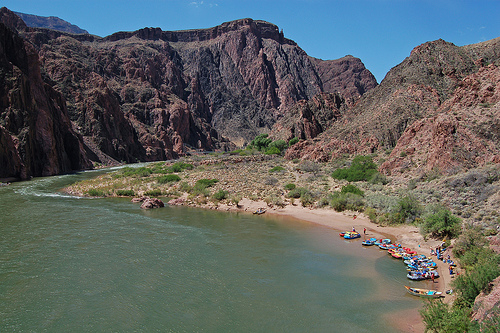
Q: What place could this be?
A: It is a beach.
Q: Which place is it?
A: It is a beach.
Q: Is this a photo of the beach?
A: Yes, it is showing the beach.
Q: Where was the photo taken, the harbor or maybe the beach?
A: It was taken at the beach.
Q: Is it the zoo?
A: No, it is the beach.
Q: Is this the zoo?
A: No, it is the beach.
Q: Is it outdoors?
A: Yes, it is outdoors.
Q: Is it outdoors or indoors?
A: It is outdoors.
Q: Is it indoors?
A: No, it is outdoors.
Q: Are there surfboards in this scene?
A: No, there are no surfboards.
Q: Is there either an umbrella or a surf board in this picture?
A: No, there are no surfboards or umbrellas.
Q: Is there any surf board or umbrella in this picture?
A: No, there are no surfboards or umbrellas.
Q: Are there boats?
A: Yes, there is a boat.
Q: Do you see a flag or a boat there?
A: Yes, there is a boat.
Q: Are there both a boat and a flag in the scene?
A: No, there is a boat but no flags.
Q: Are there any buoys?
A: No, there are no buoys.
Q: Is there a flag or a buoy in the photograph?
A: No, there are no buoys or flags.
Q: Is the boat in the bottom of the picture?
A: Yes, the boat is in the bottom of the image.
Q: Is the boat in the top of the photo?
A: No, the boat is in the bottom of the image.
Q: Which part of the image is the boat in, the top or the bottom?
A: The boat is in the bottom of the image.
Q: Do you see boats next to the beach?
A: Yes, there is a boat next to the beach.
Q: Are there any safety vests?
A: No, there are no safety vests.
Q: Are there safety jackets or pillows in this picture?
A: No, there are no safety jackets or pillows.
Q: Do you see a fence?
A: No, there are no fences.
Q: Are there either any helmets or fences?
A: No, there are no fences or helmets.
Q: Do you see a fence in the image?
A: No, there are no fences.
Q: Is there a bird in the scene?
A: No, there are no birds.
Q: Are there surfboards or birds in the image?
A: No, there are no birds or surfboards.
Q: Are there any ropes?
A: No, there are no ropes.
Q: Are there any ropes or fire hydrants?
A: No, there are no ropes or fire hydrants.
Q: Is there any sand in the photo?
A: Yes, there is sand.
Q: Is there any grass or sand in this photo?
A: Yes, there is sand.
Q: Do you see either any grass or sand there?
A: Yes, there is sand.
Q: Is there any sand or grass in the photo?
A: Yes, there is sand.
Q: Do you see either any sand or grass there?
A: Yes, there is sand.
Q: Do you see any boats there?
A: Yes, there is a boat.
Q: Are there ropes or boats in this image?
A: Yes, there is a boat.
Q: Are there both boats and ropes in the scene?
A: No, there is a boat but no ropes.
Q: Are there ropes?
A: No, there are no ropes.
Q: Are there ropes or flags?
A: No, there are no ropes or flags.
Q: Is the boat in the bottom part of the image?
A: Yes, the boat is in the bottom of the image.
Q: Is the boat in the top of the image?
A: No, the boat is in the bottom of the image.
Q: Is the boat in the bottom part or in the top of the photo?
A: The boat is in the bottom of the image.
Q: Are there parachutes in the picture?
A: No, there are no parachutes.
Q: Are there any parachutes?
A: No, there are no parachutes.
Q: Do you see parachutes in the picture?
A: No, there are no parachutes.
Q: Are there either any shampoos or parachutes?
A: No, there are no parachutes or shampoos.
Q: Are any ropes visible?
A: No, there are no ropes.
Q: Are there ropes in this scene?
A: No, there are no ropes.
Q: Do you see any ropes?
A: No, there are no ropes.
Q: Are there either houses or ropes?
A: No, there are no ropes or houses.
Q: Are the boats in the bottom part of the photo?
A: Yes, the boats are in the bottom of the image.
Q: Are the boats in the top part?
A: No, the boats are in the bottom of the image.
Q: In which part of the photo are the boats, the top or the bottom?
A: The boats are in the bottom of the image.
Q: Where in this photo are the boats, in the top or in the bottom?
A: The boats are in the bottom of the image.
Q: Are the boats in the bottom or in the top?
A: The boats are in the bottom of the image.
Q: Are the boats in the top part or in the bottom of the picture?
A: The boats are in the bottom of the image.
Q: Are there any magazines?
A: No, there are no magazines.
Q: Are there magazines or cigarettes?
A: No, there are no magazines or cigarettes.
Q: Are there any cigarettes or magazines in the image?
A: No, there are no magazines or cigarettes.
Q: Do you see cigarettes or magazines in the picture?
A: No, there are no magazines or cigarettes.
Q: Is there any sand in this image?
A: Yes, there is sand.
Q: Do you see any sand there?
A: Yes, there is sand.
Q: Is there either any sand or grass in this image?
A: Yes, there is sand.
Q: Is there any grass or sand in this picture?
A: Yes, there is sand.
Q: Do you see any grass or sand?
A: Yes, there is sand.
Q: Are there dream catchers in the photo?
A: No, there are no dream catchers.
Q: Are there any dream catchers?
A: No, there are no dream catchers.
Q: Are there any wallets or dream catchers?
A: No, there are no dream catchers or wallets.